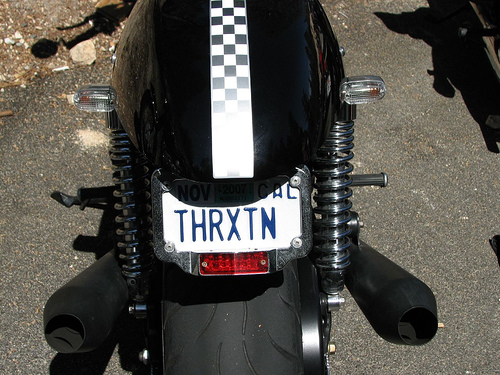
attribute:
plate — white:
[164, 192, 301, 252]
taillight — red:
[200, 250, 269, 275]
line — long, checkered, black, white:
[207, 1, 258, 176]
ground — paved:
[2, 1, 497, 370]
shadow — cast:
[375, 2, 497, 164]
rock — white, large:
[68, 37, 99, 68]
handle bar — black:
[53, 5, 131, 62]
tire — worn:
[172, 286, 299, 375]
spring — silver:
[316, 119, 359, 274]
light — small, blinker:
[345, 76, 391, 105]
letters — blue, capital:
[171, 209, 278, 243]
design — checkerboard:
[206, 5, 259, 178]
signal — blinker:
[75, 82, 114, 112]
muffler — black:
[349, 231, 441, 347]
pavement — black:
[1, 2, 498, 369]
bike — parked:
[37, 0, 431, 373]